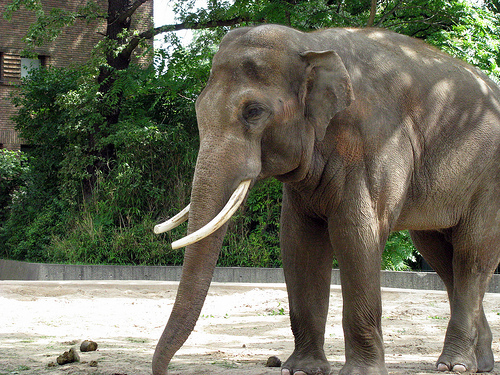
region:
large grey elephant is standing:
[152, 23, 499, 373]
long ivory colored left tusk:
[170, 179, 250, 249]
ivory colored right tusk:
[153, 203, 189, 233]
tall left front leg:
[327, 119, 412, 374]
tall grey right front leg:
[278, 180, 333, 373]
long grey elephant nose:
[152, 88, 270, 373]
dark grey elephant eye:
[242, 102, 264, 122]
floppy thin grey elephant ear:
[300, 49, 352, 140]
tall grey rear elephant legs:
[408, 160, 498, 371]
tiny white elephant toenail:
[451, 365, 466, 372]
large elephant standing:
[137, 20, 498, 372]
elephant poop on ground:
[44, 321, 128, 372]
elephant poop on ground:
[273, 355, 285, 367]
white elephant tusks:
[154, 169, 256, 254]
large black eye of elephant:
[244, 98, 269, 124]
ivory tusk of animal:
[136, 178, 261, 255]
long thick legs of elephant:
[265, 215, 497, 374]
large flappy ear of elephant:
[300, 49, 356, 136]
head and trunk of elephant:
[75, 18, 344, 357]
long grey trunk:
[137, 150, 272, 374]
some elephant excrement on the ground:
[50, 339, 96, 368]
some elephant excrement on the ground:
[266, 354, 282, 370]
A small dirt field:
[2, 275, 499, 372]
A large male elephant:
[146, 25, 498, 374]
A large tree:
[9, 0, 272, 212]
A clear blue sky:
[152, 0, 242, 82]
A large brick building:
[0, 0, 156, 157]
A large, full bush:
[12, 64, 105, 211]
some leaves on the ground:
[263, 302, 285, 318]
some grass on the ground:
[1, 333, 56, 374]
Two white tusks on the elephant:
[156, 177, 258, 249]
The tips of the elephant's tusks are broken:
[153, 221, 180, 256]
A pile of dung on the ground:
[49, 330, 105, 370]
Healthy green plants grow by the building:
[69, 77, 171, 241]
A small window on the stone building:
[11, 49, 63, 86]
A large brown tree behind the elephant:
[95, 2, 150, 159]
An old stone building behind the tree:
[0, 3, 162, 161]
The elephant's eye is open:
[245, 100, 266, 118]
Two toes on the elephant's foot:
[438, 356, 473, 373]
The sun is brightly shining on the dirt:
[32, 291, 159, 336]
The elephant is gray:
[257, 43, 477, 223]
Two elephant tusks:
[150, 173, 256, 245]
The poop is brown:
[66, 333, 101, 370]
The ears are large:
[293, 45, 362, 127]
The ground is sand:
[25, 283, 140, 370]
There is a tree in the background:
[35, 74, 177, 226]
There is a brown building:
[0, 15, 140, 193]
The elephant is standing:
[130, 28, 471, 368]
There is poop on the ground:
[40, 334, 99, 370]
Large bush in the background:
[47, 8, 481, 251]